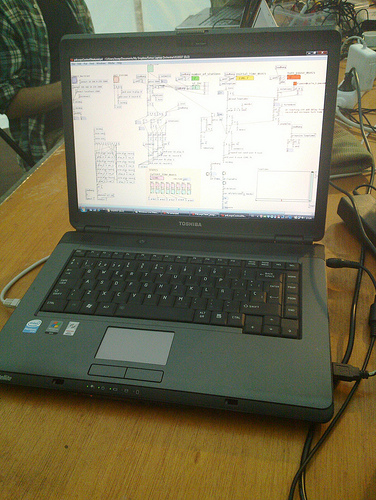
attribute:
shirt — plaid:
[0, 2, 53, 84]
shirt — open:
[10, 7, 93, 30]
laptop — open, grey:
[6, 41, 335, 354]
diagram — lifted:
[71, 62, 312, 219]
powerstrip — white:
[339, 29, 374, 120]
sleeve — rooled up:
[0, 77, 27, 105]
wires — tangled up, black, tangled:
[318, 5, 370, 35]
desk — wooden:
[8, 166, 375, 456]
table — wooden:
[3, 13, 373, 258]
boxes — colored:
[76, 77, 305, 81]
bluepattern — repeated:
[147, 173, 203, 195]